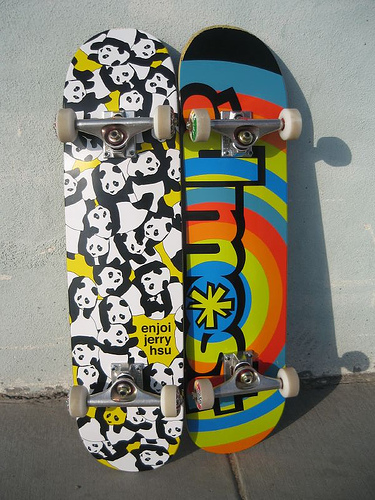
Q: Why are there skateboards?
A: Riding.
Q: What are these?
A: Skateboard.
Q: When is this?
A: Daytime.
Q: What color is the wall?
A: Gray.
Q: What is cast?
A: Shadow.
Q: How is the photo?
A: Clear.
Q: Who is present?
A: No one.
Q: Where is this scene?
A: On a wall.